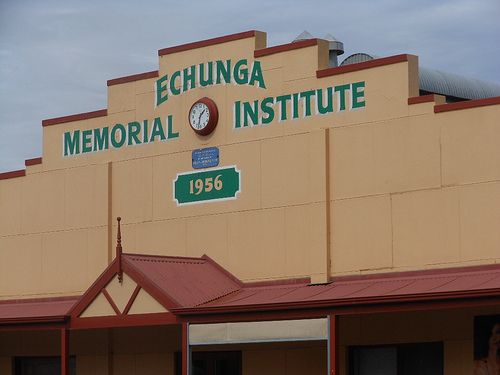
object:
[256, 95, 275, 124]
s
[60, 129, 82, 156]
letter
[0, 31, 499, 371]
building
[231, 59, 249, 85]
letter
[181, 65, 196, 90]
h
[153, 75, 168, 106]
e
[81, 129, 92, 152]
e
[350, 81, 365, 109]
e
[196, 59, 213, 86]
'u'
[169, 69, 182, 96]
c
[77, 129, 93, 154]
letter